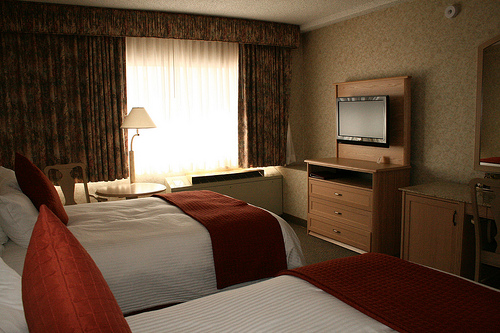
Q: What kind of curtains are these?
A: Brown curtains.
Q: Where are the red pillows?
A: On the two white beds.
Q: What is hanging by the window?
A: Curtains.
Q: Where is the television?
A: On top of a brown cabinet.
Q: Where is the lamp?
A: Above the end table.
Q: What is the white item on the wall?
A: Smoke detector.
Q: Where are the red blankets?
A: At the foot of the beds.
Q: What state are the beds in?
A: Made.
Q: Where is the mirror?
A: Above the desk.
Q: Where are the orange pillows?
A: On the beds.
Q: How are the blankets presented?
A: Laid over feet of beds.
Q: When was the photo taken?
A: Daytime.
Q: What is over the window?
A: Curtains.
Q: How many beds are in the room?
A: Two.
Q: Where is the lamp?
A: Table.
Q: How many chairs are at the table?
A: One.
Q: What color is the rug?
A: Brown.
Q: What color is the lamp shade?
A: White.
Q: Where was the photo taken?
A: In a hotel room.